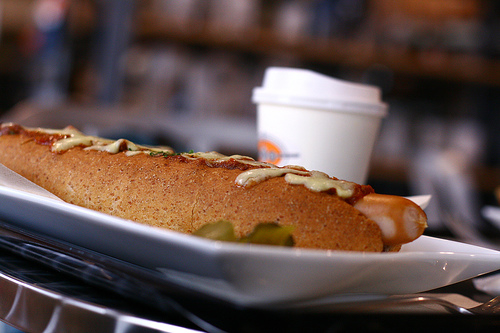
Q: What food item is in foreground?
A: Hotdog.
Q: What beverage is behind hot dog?
A: Coffee.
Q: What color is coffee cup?
A: White.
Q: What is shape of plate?
A: Rectangle.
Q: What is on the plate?
A: Hot Dog.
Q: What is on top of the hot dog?
A: Cheese.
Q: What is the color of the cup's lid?
A: White.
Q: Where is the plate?
A: On the table.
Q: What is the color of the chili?
A: Red.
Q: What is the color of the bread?
A: Brown.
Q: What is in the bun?
A: Hot dog.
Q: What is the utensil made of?
A: Stainless steel.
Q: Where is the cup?
A: In front of the plate.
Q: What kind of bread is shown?
A: Wheat.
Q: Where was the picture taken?
A: In a restaurant.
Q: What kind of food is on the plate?
A: Hot dog.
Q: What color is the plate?
A: White.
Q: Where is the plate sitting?
A: On a tray.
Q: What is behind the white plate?
A: A coffee cup.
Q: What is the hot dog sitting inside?
A: A bun.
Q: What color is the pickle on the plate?
A: Green.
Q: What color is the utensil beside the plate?
A: Silver.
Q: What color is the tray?
A: Black.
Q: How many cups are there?
A: 1.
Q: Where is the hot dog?
A: On the bun.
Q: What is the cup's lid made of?
A: Plastic.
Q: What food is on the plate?
A: Hotdog.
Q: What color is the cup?
A: White.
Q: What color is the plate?
A: White.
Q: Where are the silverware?
A: Next to the plate.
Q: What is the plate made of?
A: Ceramic.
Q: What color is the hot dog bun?
A: Brown.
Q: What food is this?
A: Hot Dog.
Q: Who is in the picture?
A: No one.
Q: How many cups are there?
A: One.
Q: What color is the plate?
A: White ceramic.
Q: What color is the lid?
A: White plastic.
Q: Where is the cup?
A: Behind the plate.